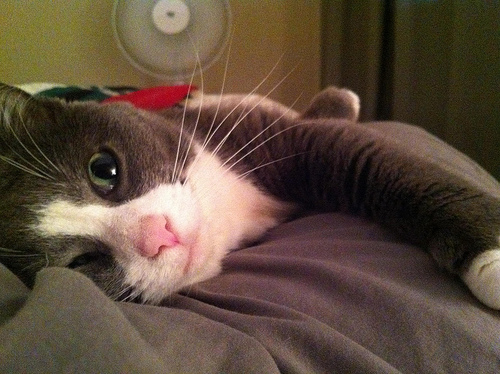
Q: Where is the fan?
A: Background.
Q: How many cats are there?
A: One.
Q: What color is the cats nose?
A: Pink.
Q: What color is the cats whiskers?
A: White.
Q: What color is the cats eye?
A: Green.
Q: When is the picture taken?
A: Day time.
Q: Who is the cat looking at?
A: The person taking the picture.